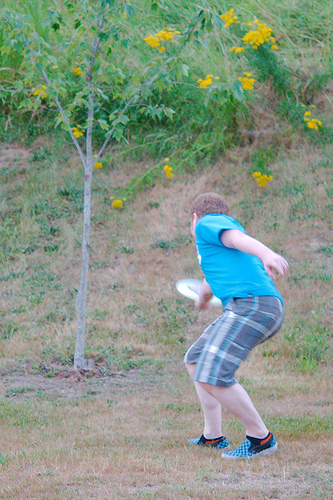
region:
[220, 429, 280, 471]
bright blue shoes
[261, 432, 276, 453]
orange stripe on the socks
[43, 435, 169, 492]
grass is mostly dead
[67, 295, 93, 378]
tree trunk is very thin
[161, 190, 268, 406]
boy is catching the frisbee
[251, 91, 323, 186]
yellow flowers on the tree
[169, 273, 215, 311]
frisbee is being caught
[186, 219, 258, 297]
boy is wearing a blue shirt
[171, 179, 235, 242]
the head of a boy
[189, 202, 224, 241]
the ear of a boy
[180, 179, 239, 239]
the hair of a boy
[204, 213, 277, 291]
the arm of a boy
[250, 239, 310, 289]
the hand of a boy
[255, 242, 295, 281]
the fingers of a boy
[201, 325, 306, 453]
the leg of a boy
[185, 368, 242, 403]
the knee of a boy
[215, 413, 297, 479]
the foot of a boy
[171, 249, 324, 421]
a boy wearing shorts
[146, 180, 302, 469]
the boy catching frisbee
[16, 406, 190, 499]
the grass is dry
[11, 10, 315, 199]
yellow blossoms on the tree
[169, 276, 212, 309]
the frisbee is white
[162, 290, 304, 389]
the boy wearing plaid shorts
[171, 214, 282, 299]
the boy wearing blue shirt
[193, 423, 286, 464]
the boy wearing blue sneakers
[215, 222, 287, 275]
arm of the boy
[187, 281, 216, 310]
arm of the boy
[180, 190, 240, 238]
the head of the boy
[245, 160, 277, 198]
yellow flower on tree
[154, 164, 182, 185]
yellow flower on tree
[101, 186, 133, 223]
yellow flower on tree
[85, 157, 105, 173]
yellow flower on tree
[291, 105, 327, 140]
yellow flower on tree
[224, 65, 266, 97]
yellow flower on tree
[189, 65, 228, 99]
yellow flower on tree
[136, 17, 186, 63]
yellow flower on tree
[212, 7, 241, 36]
yellow flower on tree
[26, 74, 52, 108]
yellow flower on tree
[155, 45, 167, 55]
yellow flower in field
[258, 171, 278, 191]
yellow flower in field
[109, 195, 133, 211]
yellow flower in field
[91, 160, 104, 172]
yellow flower in field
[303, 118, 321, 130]
yellow flower in field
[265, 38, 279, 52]
yellow flower in field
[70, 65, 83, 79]
yellow flower in field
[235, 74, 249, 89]
yellow flower in field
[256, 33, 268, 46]
yellow flower in field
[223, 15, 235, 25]
yellow flower in field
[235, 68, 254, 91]
bunch of yellow flowers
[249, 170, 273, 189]
bunch of yellow flowers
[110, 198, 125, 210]
bunch of yellow flowers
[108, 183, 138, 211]
yellow flowers attached to a small tree branch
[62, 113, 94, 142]
yellow flowers attached to a small tree branch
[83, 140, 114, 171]
yellow flowers attached to a small tree branch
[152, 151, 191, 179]
yellow flowers attached to a small tree branch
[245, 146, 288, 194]
yellow flowers attached to a small tree branch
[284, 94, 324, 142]
yellow flowers attached to a small tree branch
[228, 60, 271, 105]
yellow flowers attached to a small tree branch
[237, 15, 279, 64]
yellow flowers attached to a small tree branch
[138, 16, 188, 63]
yellow flowers attached to a small tree branch